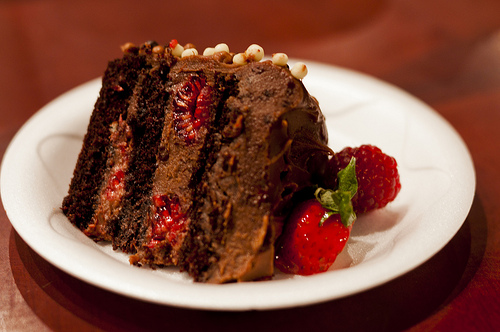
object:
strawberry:
[274, 155, 357, 277]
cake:
[60, 39, 335, 284]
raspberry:
[324, 144, 401, 217]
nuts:
[290, 61, 308, 80]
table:
[1, 0, 499, 330]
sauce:
[172, 75, 210, 143]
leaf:
[338, 191, 353, 228]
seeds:
[318, 255, 324, 262]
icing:
[208, 60, 328, 281]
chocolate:
[110, 59, 172, 253]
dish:
[1, 51, 478, 310]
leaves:
[336, 155, 358, 200]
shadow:
[8, 191, 489, 331]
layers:
[146, 62, 222, 262]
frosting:
[92, 119, 134, 238]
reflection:
[296, 208, 311, 242]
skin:
[275, 198, 358, 276]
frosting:
[201, 64, 327, 285]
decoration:
[123, 37, 308, 80]